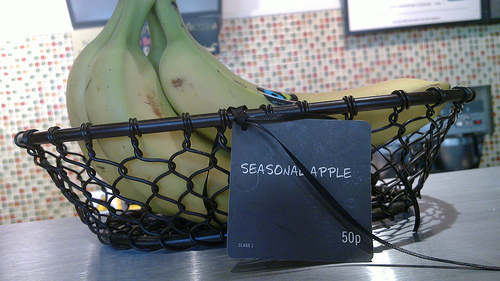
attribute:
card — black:
[226, 122, 374, 263]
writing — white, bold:
[240, 161, 351, 179]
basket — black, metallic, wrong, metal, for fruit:
[15, 85, 477, 252]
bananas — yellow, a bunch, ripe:
[68, 1, 455, 224]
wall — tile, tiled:
[4, 7, 499, 227]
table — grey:
[2, 169, 497, 280]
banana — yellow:
[154, 3, 454, 149]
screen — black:
[67, 2, 223, 30]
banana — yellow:
[66, 2, 150, 209]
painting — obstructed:
[343, 0, 499, 34]